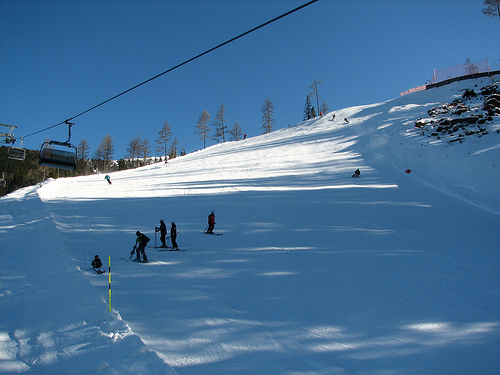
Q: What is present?
A: Snow.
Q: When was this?
A: Daytime.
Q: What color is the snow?
A: White.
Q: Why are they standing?
A: To ski.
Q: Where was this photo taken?
A: On snow.